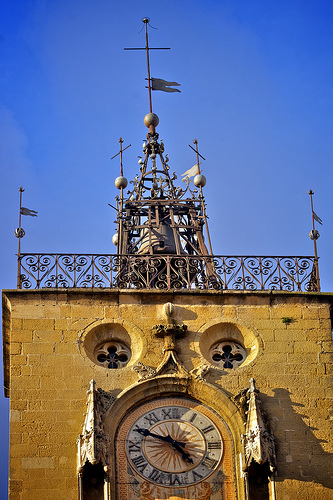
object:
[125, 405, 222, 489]
clock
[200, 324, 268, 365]
cross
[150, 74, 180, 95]
flag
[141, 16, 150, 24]
top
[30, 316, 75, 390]
stone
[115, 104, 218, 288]
tower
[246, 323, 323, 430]
wall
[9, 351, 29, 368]
stones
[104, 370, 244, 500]
door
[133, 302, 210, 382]
statue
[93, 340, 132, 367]
window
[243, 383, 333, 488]
shadow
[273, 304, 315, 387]
brick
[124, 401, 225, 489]
roman numerals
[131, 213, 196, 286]
bell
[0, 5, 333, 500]
building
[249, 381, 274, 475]
shape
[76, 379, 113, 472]
shape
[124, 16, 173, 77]
cross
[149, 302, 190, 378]
decoration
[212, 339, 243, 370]
window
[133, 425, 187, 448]
hand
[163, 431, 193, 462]
hand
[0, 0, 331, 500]
sky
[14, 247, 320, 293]
railing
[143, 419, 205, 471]
dial